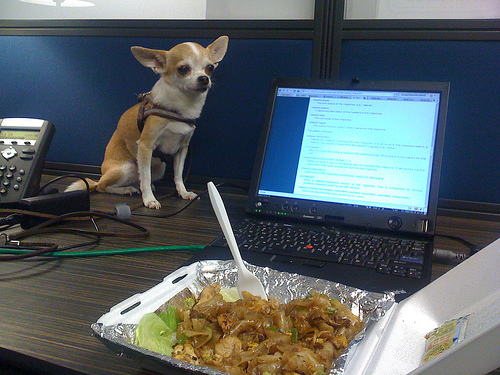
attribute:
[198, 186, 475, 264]
cable — black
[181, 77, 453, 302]
computer — powered on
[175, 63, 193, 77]
eye — brown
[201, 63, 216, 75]
eye — brown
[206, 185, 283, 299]
fork — plastic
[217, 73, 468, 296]
laptop — black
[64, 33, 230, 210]
chihuahua — brown, white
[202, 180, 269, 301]
plastic fork — white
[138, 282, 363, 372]
food — take out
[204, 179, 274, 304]
fork — white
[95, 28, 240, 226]
dog — tan, white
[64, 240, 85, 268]
cable — brown, green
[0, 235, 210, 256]
cable — green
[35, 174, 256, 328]
table — wooden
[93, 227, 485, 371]
container — styrofoam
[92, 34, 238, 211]
dog — small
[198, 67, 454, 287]
computer — laptop